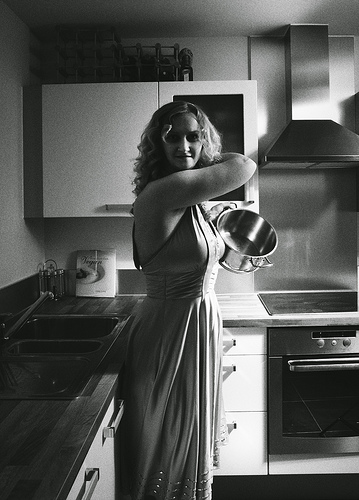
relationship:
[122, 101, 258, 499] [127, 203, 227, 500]
lady wearing dress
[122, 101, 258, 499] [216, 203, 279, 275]
lady holding pot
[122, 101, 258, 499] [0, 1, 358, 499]
lady standing in kitchen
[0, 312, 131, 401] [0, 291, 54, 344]
sink with faucet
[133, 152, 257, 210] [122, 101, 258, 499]
arm of lady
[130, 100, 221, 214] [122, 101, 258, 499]
hair of lady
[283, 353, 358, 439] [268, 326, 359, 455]
window of oven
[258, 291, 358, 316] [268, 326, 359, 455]
stove and oven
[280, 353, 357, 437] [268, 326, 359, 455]
door of oven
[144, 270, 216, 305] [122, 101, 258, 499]
mid waist of lady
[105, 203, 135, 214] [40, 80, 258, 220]
handle of cabinets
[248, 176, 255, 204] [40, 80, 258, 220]
handle of cabinets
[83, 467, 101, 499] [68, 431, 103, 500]
handle of cabinet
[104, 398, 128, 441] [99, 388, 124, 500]
handle of cabinet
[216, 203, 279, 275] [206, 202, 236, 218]
pot held in hand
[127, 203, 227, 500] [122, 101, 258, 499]
dress worn on lady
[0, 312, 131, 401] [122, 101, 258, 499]
sink behind lady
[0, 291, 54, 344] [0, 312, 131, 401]
faucet of sink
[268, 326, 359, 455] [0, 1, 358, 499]
oven in kitchen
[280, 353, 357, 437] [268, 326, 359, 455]
door on front of oven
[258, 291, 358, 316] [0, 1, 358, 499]
stove placed in kitchen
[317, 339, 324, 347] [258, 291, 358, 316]
knob for stove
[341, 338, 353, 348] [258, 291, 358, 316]
knob for stove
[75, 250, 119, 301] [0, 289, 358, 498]
cook book in back of counter top